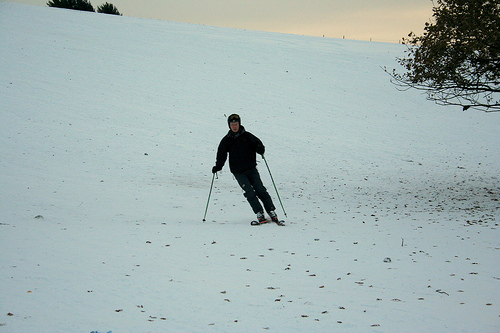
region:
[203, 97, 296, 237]
skier on a slop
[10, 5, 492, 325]
a hill covered with snow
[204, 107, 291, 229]
skier wears black clothes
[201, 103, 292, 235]
skier has a black helmet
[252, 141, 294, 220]
snow pole on left hand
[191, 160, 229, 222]
snow pole on right hand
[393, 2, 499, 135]
branches of a tree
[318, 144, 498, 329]
debris on the snow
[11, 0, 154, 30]
trees on top the hill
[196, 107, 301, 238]
skier is bend on left side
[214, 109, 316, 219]
person skiing down hill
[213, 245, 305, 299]
pattern of leaves on snow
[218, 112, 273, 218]
person wearing gray pants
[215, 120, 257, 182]
person wearing black jacket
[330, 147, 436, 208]
black objects on snow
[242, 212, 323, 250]
person using black skis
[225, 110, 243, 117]
person wearing black cap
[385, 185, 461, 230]
light shadow of tree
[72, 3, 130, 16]
green trees in background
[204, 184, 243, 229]
person using ski poles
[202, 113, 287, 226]
man is skiing down a hill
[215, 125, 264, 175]
man wearing black coat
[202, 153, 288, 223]
man holding ski poles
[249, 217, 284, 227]
skis under man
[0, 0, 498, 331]
hill is snow covered and steep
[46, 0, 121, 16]
trees behind hill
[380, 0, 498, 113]
tree next to man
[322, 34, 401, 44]
fence on hill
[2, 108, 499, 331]
leaves on the snow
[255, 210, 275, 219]
man wearing white shoe laces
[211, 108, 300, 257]
Man skiing down the hill.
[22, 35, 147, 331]
Snow on the ground.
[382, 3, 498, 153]
Tree on the mountain.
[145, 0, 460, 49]
Sky in the background.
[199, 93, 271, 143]
Helmet on a man's head.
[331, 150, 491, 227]
Tree leaves on the ground.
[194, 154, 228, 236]
Ski pole in a man's hand.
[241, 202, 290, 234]
Skis on a man's feet.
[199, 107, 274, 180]
A man wearing a ski jacket.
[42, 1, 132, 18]
Trees on the mountain top.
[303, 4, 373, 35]
this is the sky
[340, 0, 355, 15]
the sky is blue in color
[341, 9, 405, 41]
the sky is full of clouds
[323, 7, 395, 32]
the clouds are white in color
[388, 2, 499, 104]
this is a tree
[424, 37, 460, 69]
the leaves are green in color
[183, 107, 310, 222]
this is a person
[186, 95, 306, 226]
the person is skating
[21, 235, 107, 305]
this is the snow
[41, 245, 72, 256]
the snow is white in color